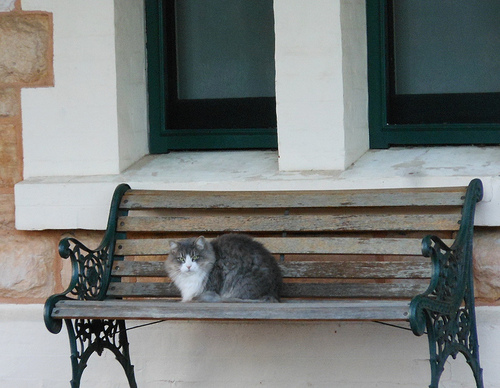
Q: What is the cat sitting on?
A: Bench.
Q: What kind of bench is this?
A: Wood and metal bench.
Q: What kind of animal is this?
A: Cat.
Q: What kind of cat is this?
A: Grey and white.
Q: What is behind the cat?
A: Two black windows.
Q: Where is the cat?
A: On the bench.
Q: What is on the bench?
A: A cat.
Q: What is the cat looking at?
A: The camera.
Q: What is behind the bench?
A: A building.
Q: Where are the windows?
A: Behind the bench.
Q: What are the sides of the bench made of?
A: Metal.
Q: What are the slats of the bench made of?
A: Wood.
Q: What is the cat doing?
A: Sitting on a bench.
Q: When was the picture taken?
A: Day time.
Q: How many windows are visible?
A: Two.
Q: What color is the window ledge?
A: White.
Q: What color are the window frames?
A: A dark shade of green.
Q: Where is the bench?
A: Set in front of the windows.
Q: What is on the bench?
A: A cat.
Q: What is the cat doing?
A: Sitting.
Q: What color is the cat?
A: Gray and white.